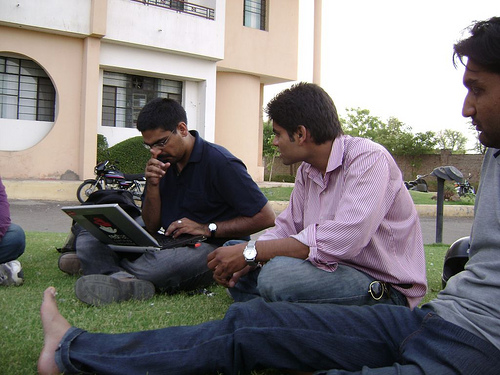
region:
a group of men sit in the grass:
[27, 50, 499, 368]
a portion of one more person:
[0, 160, 26, 292]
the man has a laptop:
[63, 166, 218, 248]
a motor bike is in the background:
[76, 155, 186, 205]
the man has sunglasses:
[364, 275, 404, 300]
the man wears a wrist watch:
[240, 235, 260, 270]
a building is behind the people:
[8, 7, 328, 219]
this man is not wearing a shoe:
[23, 285, 90, 373]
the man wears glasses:
[140, 127, 181, 152]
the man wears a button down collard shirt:
[261, 141, 420, 297]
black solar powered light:
[427, 159, 469, 244]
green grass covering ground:
[126, 303, 198, 325]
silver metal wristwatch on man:
[241, 240, 266, 271]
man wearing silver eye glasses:
[131, 126, 182, 156]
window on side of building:
[230, 0, 287, 37]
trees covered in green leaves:
[383, 116, 455, 151]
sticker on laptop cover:
[83, 212, 132, 248]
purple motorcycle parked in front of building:
[74, 158, 149, 200]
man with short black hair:
[235, 70, 364, 190]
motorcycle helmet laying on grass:
[425, 220, 475, 292]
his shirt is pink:
[314, 165, 391, 240]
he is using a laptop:
[67, 195, 217, 273]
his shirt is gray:
[436, 177, 492, 367]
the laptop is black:
[45, 195, 154, 282]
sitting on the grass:
[31, 202, 376, 326]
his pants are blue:
[115, 305, 422, 355]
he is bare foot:
[17, 274, 83, 372]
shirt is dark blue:
[153, 152, 251, 222]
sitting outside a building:
[1, 5, 291, 166]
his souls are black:
[79, 271, 154, 305]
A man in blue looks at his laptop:
[60, 94, 224, 248]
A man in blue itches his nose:
[130, 89, 253, 195]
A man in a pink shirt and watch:
[245, 72, 431, 279]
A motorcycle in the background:
[452, 173, 479, 196]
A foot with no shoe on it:
[31, 277, 91, 370]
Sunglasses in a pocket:
[362, 271, 413, 302]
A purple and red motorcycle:
[72, 154, 146, 204]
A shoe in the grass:
[71, 269, 161, 311]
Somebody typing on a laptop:
[60, 194, 212, 250]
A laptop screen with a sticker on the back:
[55, 197, 162, 254]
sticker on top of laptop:
[81, 209, 139, 250]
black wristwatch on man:
[197, 218, 228, 240]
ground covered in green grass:
[3, 296, 37, 373]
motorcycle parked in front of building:
[68, 162, 148, 205]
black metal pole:
[432, 180, 447, 245]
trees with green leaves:
[343, 102, 403, 137]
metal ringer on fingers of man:
[174, 218, 188, 229]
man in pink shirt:
[252, 77, 432, 298]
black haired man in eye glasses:
[124, 89, 194, 172]